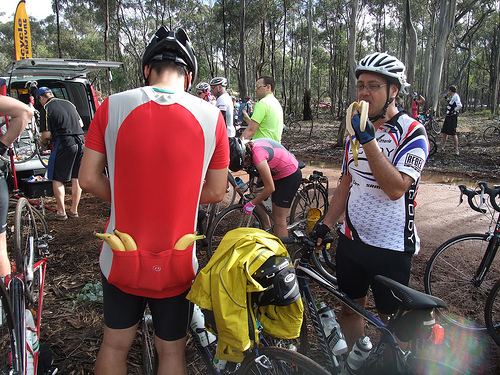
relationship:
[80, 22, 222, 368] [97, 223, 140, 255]
man with bananas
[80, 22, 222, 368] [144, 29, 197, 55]
man wearing black helmet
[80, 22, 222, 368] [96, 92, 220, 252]
man wearing red shirt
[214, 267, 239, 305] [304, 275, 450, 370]
yellow jacket on bike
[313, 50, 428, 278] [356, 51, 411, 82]
man wearing white helmet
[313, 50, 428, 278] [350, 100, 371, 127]
man eating a banana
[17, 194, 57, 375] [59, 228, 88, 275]
bike turn down on ground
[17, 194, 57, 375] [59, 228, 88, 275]
bike down on ground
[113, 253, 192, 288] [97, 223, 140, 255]
pockets with bananas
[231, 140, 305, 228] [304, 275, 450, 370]
woman working on bike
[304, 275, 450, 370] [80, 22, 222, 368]
bike helmet on man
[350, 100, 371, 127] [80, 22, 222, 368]
banana being eaten by man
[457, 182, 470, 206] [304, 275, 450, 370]
handbreaks on a bike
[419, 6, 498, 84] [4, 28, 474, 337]
woods around bicyclist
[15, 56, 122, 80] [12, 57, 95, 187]
hatchback on vehicle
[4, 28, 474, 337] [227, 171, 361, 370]
bicyclist about to ride bikes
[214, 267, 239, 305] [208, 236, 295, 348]
yellow rain jacket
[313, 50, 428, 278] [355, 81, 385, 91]
man wearing glasses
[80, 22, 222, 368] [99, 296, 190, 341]
man wearing black shorts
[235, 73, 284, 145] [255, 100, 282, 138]
people wearing a green shirt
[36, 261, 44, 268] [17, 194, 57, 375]
red upside down bike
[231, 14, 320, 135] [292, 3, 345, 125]
people standing in forrest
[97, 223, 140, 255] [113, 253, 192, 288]
bananas in back pockets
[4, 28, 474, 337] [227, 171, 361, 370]
bicyclist ready to ride bikes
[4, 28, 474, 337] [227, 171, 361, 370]
bicyclist preparing bikes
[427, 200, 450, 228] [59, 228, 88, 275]
dirt on ground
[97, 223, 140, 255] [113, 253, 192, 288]
bananas in pockets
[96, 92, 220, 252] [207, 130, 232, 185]
shirt has short sleeve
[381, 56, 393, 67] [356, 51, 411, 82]
white safety helmet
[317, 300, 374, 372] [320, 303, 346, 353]
bottles of water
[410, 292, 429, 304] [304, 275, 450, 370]
black seat on bike